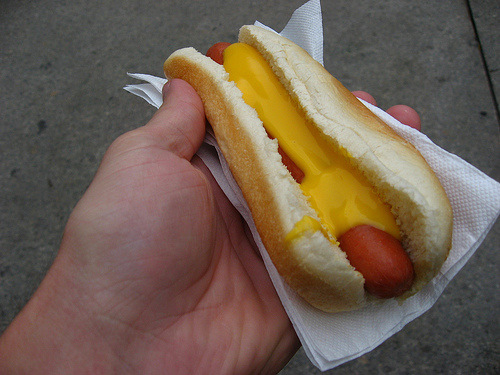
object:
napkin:
[120, 0, 500, 375]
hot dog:
[199, 41, 416, 301]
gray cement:
[0, 0, 500, 375]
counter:
[0, 0, 500, 375]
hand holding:
[96, 0, 500, 375]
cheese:
[220, 41, 400, 248]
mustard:
[219, 41, 403, 246]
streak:
[453, 0, 500, 120]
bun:
[163, 23, 453, 313]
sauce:
[219, 40, 406, 251]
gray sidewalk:
[0, 0, 500, 375]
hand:
[0, 75, 421, 375]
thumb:
[140, 76, 207, 163]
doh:
[117, 0, 500, 375]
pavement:
[0, 0, 500, 375]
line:
[461, 0, 500, 122]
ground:
[0, 0, 500, 375]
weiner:
[162, 18, 457, 313]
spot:
[35, 119, 47, 136]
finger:
[385, 105, 421, 133]